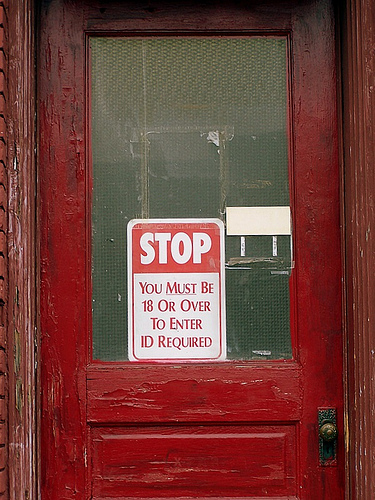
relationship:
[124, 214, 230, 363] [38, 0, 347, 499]
sign on front of door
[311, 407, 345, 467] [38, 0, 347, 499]
door knob on door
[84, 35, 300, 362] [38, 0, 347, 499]
pane on door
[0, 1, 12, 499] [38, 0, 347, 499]
wall next to door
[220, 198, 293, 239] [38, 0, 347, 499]
paper on door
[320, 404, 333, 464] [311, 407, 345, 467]
plate behind door knob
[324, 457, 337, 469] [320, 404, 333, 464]
paint on plate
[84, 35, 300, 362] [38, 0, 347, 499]
pane on front of door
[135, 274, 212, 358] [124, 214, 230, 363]
lettering on front of sign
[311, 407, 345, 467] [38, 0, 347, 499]
door knob of door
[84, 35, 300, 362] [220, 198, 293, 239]
pane with paper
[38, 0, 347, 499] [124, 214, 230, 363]
door with sign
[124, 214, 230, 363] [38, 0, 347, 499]
sign on door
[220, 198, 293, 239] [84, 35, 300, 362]
paper on pane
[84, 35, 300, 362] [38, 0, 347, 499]
pane to door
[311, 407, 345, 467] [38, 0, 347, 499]
door knob to door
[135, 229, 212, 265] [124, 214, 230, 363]
stop on sign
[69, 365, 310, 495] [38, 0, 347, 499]
panels of door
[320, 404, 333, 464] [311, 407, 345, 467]
plate of door knob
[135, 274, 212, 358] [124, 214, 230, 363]
lettering on sign